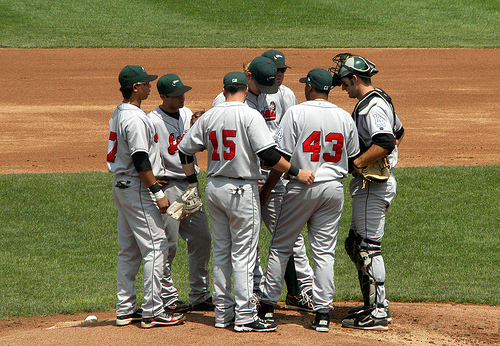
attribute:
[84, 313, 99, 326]
ball — small, white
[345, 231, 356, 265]
pad — large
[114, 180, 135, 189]
glove — white, blue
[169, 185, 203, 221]
glove — white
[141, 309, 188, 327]
sneaker — black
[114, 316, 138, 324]
sneaker — black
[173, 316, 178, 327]
trim — red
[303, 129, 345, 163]
number — large, red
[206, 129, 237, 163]
number — large, red, 15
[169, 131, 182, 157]
number — large, red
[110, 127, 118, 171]
number — large, red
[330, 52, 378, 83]
helmet — blue, green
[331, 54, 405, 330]
player — catcher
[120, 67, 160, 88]
cap — green, black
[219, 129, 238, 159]
five — red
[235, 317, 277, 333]
cleat — grey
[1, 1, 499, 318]
grass — green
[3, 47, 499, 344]
dirt — brown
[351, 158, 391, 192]
player's — brown, leather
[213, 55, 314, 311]
man — talking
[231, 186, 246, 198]
glove — white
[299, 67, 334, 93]
cap — green, black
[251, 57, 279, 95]
cap — green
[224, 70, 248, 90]
cap — green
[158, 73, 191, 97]
cap — green